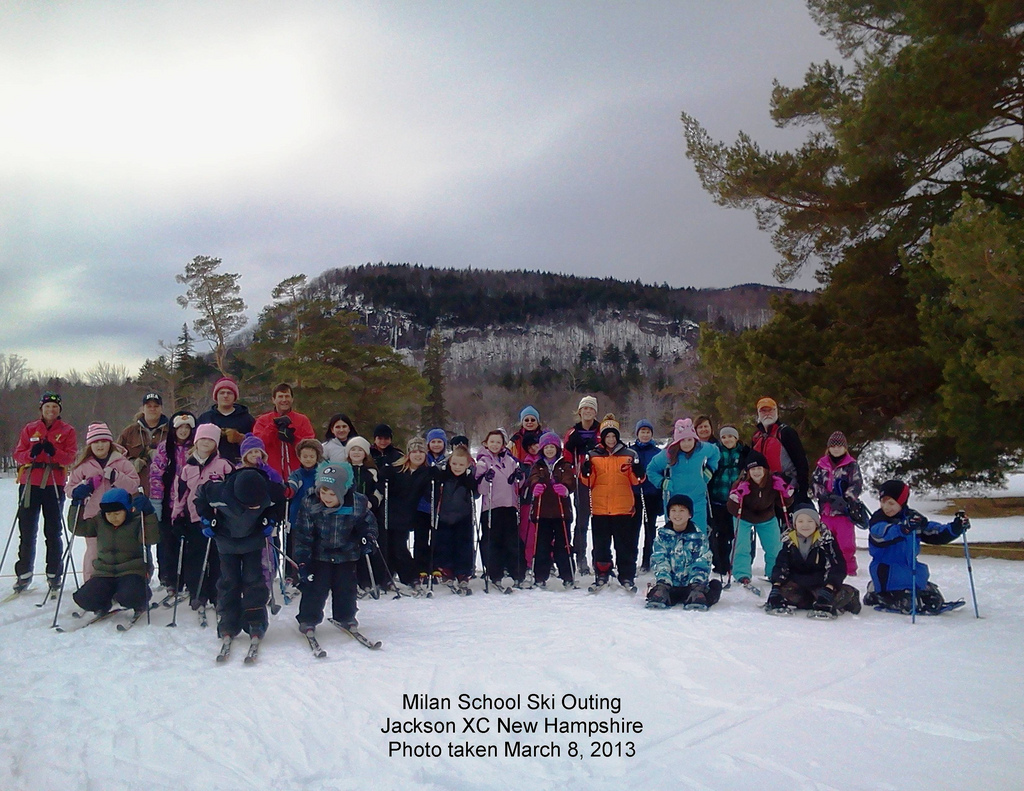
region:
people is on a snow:
[3, 362, 993, 682]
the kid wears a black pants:
[287, 450, 396, 686]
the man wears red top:
[10, 385, 81, 610]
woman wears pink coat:
[173, 416, 231, 514]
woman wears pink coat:
[468, 423, 525, 519]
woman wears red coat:
[253, 375, 317, 470]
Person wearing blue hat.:
[515, 402, 545, 423]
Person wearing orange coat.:
[593, 440, 639, 514]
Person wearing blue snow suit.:
[862, 511, 938, 589]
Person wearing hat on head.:
[752, 389, 782, 419]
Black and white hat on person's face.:
[142, 383, 178, 434]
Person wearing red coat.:
[15, 421, 79, 485]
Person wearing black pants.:
[214, 552, 287, 639]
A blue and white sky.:
[3, 5, 870, 376]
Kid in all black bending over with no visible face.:
[191, 465, 291, 640]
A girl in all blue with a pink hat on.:
[645, 419, 722, 538]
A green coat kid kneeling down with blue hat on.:
[65, 478, 164, 622]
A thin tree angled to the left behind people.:
[178, 254, 246, 376]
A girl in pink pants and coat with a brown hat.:
[806, 429, 861, 576]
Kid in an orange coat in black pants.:
[579, 413, 647, 585]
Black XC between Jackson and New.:
[460, 715, 492, 736]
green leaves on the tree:
[913, 239, 987, 304]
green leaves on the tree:
[844, 255, 886, 351]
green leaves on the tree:
[296, 325, 338, 355]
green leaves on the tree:
[378, 347, 401, 373]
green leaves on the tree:
[853, 247, 870, 302]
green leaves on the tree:
[910, 348, 978, 422]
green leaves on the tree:
[893, 79, 923, 96]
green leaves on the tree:
[180, 318, 258, 383]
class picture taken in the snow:
[15, 366, 973, 624]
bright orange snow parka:
[582, 409, 639, 520]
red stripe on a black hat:
[878, 472, 917, 530]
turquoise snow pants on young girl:
[730, 518, 785, 577]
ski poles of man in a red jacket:
[3, 454, 84, 628]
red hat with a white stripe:
[205, 365, 237, 420]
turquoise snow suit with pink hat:
[647, 409, 720, 571]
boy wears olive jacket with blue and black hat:
[69, 482, 158, 582]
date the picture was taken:
[502, 731, 643, 766]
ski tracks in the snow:
[6, 561, 1012, 789]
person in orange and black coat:
[558, 399, 658, 593]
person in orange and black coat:
[532, 397, 678, 603]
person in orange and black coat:
[560, 418, 659, 597]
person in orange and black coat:
[550, 404, 662, 595]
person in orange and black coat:
[557, 397, 657, 607]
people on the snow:
[17, 160, 918, 660]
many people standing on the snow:
[44, 268, 977, 686]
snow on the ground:
[97, 509, 766, 778]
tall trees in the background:
[115, 89, 697, 788]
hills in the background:
[268, 165, 1021, 619]